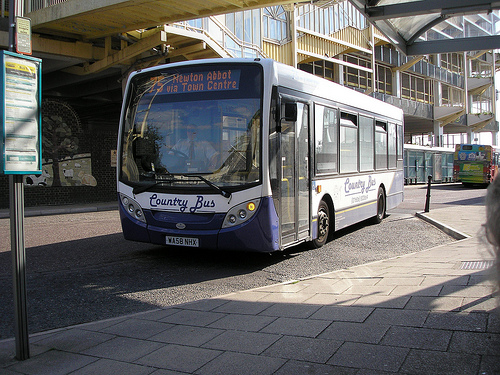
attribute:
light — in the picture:
[225, 200, 257, 226]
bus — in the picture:
[121, 70, 419, 245]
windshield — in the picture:
[110, 46, 284, 221]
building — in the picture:
[440, 136, 497, 189]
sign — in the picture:
[2, 52, 43, 175]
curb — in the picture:
[334, 275, 459, 338]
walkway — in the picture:
[11, 3, 428, 59]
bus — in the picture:
[111, 53, 427, 264]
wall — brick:
[0, 79, 117, 204]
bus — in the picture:
[104, 47, 420, 279]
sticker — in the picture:
[16, 13, 32, 55]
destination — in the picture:
[140, 68, 257, 96]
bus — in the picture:
[134, 38, 441, 260]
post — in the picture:
[8, 3, 32, 373]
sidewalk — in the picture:
[308, 265, 448, 370]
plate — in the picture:
[151, 222, 205, 251]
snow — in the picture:
[110, 60, 422, 280]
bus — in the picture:
[118, 50, 388, 247]